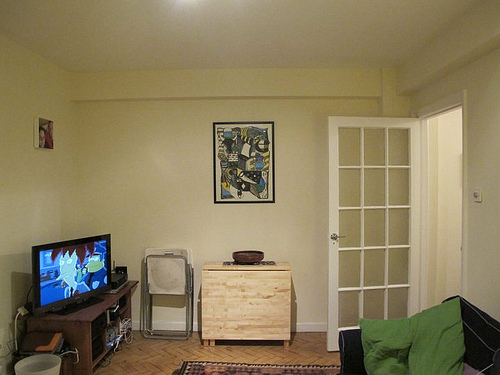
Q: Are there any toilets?
A: No, there are no toilets.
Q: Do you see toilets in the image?
A: No, there are no toilets.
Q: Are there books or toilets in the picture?
A: No, there are no toilets or books.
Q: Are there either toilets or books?
A: No, there are no toilets or books.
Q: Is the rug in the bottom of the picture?
A: Yes, the rug is in the bottom of the image.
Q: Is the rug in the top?
A: No, the rug is in the bottom of the image.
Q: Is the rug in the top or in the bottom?
A: The rug is in the bottom of the image.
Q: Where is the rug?
A: The rug is on the floor.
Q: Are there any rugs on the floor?
A: Yes, there is a rug on the floor.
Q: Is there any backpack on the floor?
A: No, there is a rug on the floor.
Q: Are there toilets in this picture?
A: No, there are no toilets.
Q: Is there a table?
A: Yes, there is a table.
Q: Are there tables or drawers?
A: Yes, there is a table.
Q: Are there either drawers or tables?
A: Yes, there is a table.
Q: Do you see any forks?
A: No, there are no forks.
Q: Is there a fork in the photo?
A: No, there are no forks.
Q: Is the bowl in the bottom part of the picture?
A: Yes, the bowl is in the bottom of the image.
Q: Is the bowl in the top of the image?
A: No, the bowl is in the bottom of the image.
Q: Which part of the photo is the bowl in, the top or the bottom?
A: The bowl is in the bottom of the image.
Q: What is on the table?
A: The bowl is on the table.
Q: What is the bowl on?
A: The bowl is on the table.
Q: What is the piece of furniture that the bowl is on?
A: The piece of furniture is a table.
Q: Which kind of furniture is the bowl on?
A: The bowl is on the table.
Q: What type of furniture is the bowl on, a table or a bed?
A: The bowl is on a table.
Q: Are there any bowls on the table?
A: Yes, there is a bowl on the table.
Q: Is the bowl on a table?
A: Yes, the bowl is on a table.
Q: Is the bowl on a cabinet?
A: No, the bowl is on a table.